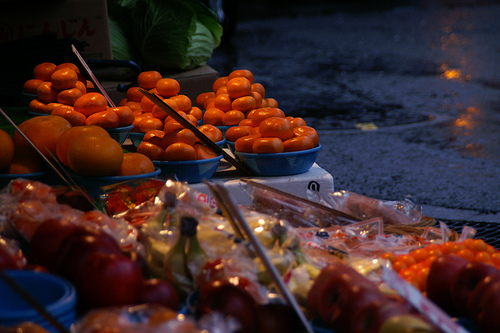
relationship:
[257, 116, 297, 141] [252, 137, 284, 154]
here is another tomato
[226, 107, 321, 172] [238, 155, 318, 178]
mandarin oranges in blue bowl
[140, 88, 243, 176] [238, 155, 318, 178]
wooden stick next to blue bowl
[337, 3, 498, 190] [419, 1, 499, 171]
reflection of light on ground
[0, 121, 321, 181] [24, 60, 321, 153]
bowls of oranges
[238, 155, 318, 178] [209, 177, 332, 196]
blue bowl full of oranges on table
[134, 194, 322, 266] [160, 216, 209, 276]
closest two bananas that are attached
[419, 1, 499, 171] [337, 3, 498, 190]
light reflecting on a grey road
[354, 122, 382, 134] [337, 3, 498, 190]
metal grate in road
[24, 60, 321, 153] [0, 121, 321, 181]
oranges in bowls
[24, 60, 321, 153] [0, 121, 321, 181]
oranges are in bowls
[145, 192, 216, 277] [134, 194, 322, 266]
bananas are colored yellow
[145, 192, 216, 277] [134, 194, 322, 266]
bananas in bags